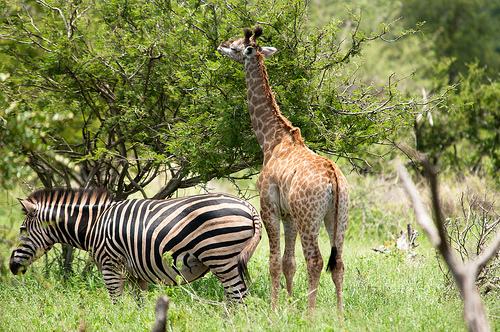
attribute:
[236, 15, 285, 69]
horns — small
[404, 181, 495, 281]
bush — dead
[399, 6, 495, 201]
trees — background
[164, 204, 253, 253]
stripe — white , Black